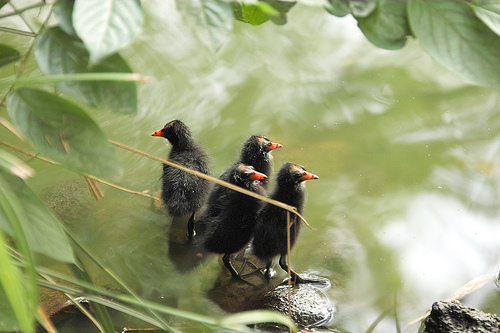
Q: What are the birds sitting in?
A: A tree.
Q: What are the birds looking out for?
A: Predators.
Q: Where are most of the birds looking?
A: To the right.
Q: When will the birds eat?
A: After catching food.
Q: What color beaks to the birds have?
A: Orange.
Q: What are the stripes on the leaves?
A: Veins.